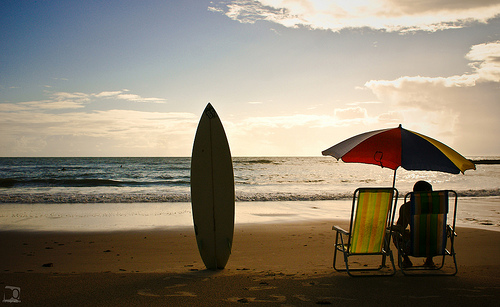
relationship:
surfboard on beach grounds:
[192, 98, 235, 274] [0, 196, 500, 307]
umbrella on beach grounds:
[319, 122, 482, 271] [0, 196, 500, 307]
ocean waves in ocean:
[0, 157, 499, 202] [1, 158, 496, 202]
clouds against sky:
[2, 1, 500, 148] [0, 4, 499, 154]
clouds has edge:
[206, 0, 499, 31] [369, 45, 500, 117]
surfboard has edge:
[192, 104, 235, 270] [190, 97, 235, 271]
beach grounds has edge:
[0, 196, 500, 307] [3, 188, 498, 219]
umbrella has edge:
[319, 122, 482, 271] [318, 150, 477, 175]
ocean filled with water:
[1, 158, 496, 202] [11, 152, 500, 197]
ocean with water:
[1, 158, 496, 202] [11, 152, 500, 197]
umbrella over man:
[319, 122, 482, 271] [393, 181, 439, 267]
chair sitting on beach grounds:
[330, 185, 401, 278] [0, 196, 500, 307]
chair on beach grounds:
[330, 185, 401, 278] [0, 196, 500, 307]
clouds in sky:
[206, 0, 499, 31] [0, 4, 499, 154]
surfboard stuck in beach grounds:
[192, 98, 235, 274] [0, 196, 500, 307]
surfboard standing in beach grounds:
[192, 98, 235, 274] [0, 196, 500, 307]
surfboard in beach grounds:
[192, 98, 235, 274] [0, 196, 500, 307]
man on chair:
[393, 181, 459, 265] [395, 187, 458, 277]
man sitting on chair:
[393, 181, 459, 265] [330, 185, 401, 278]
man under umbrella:
[393, 181, 459, 265] [319, 122, 482, 271]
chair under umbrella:
[330, 185, 401, 278] [319, 122, 482, 271]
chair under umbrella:
[395, 187, 458, 277] [319, 122, 482, 271]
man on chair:
[393, 181, 459, 265] [330, 185, 401, 278]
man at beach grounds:
[393, 181, 459, 265] [0, 196, 500, 307]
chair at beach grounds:
[330, 185, 401, 278] [0, 196, 500, 307]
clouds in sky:
[2, 1, 500, 148] [0, 4, 499, 154]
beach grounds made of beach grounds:
[3, 190, 500, 299] [0, 196, 500, 307]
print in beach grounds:
[134, 266, 296, 296] [0, 196, 500, 307]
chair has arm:
[330, 185, 401, 278] [331, 220, 350, 236]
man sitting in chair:
[393, 181, 439, 267] [390, 190, 458, 276]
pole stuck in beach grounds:
[382, 169, 399, 267] [0, 196, 500, 307]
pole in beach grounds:
[382, 169, 399, 267] [0, 196, 500, 307]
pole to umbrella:
[382, 169, 399, 267] [319, 122, 482, 271]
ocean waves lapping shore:
[5, 165, 498, 202] [0, 224, 499, 298]